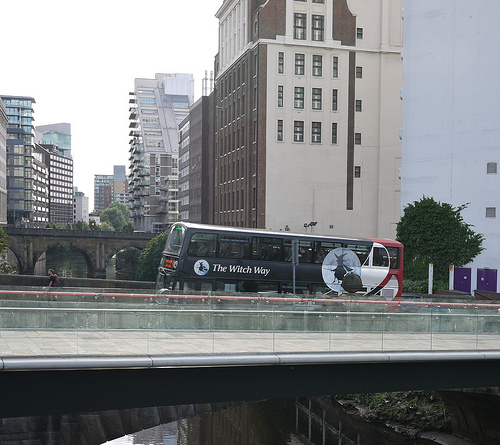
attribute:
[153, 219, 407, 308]
bus — double decker, behind, large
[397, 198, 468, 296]
tree — green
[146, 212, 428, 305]
bus — black, double decker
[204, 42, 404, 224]
building — brown, big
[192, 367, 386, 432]
water — under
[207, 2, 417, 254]
building — brown, white, behind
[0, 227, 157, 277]
bridge — across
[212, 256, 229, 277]
print — white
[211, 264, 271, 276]
print — white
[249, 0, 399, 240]
building — tan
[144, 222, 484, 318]
bus — reading